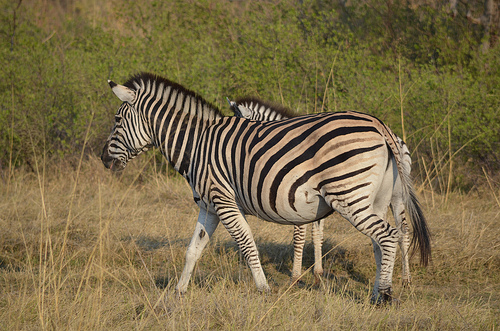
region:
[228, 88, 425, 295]
baby zebra walking in tall grass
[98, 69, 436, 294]
adult zebra walking in tall grass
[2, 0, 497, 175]
green bushes and grass in background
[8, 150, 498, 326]
tall brown grass in foreground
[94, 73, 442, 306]
black and white animal in field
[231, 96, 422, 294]
black and white animal in field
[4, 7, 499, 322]
sunny daytime outdoor field scene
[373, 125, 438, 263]
long tail with black ends of zebra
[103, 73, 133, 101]
white pointy ear with black tip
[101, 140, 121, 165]
black nose on white and black body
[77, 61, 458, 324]
two zebras in the grass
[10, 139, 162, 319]
the tall blades of grass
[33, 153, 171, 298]
the grass is dry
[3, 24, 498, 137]
the green bushes behind the zebras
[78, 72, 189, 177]
the head of the zebra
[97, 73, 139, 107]
the ear of the zebra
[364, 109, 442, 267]
the tail of the zebra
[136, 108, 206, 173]
the neck of the zebra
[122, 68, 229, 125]
the mane of the zebra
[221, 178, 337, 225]
the stomach of the zebra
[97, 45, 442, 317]
a herd of zebra in a field.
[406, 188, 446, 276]
a black tail on a zebra.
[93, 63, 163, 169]
the head of a zebra.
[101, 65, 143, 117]
a left ear on a zebra.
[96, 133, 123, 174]
a nose on a zebra.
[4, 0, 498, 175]
a field of green plants.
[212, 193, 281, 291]
a left leg of a zebra.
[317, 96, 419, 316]
a butt on a zebra.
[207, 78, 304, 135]
a Mohawk on a zebra.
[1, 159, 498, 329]
a field of dirt.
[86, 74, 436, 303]
a zebra walking through a field.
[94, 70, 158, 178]
a black and white stripe zebra head.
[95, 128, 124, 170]
the mouth of a zebra.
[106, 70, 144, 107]
a left zebra ear.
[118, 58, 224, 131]
a black and white zebra mohawk.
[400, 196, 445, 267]
a dark colored zebra tail.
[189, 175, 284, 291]
a left front zebra leg.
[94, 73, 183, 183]
a zebra head.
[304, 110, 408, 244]
the ass of a zebra.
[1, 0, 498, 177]
A field of green grass.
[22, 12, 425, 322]
two zebras in the wild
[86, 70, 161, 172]
the head of a zebra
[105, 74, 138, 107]
the ear of a zebra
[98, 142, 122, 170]
the nose of a zebra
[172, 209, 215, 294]
the front leg of a zebra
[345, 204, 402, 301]
the rear leg of a zebra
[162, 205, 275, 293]
the front legs of a zebra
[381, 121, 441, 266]
the tail of a zebra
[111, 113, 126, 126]
the eye of a zebra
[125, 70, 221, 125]
the mane of a zebra